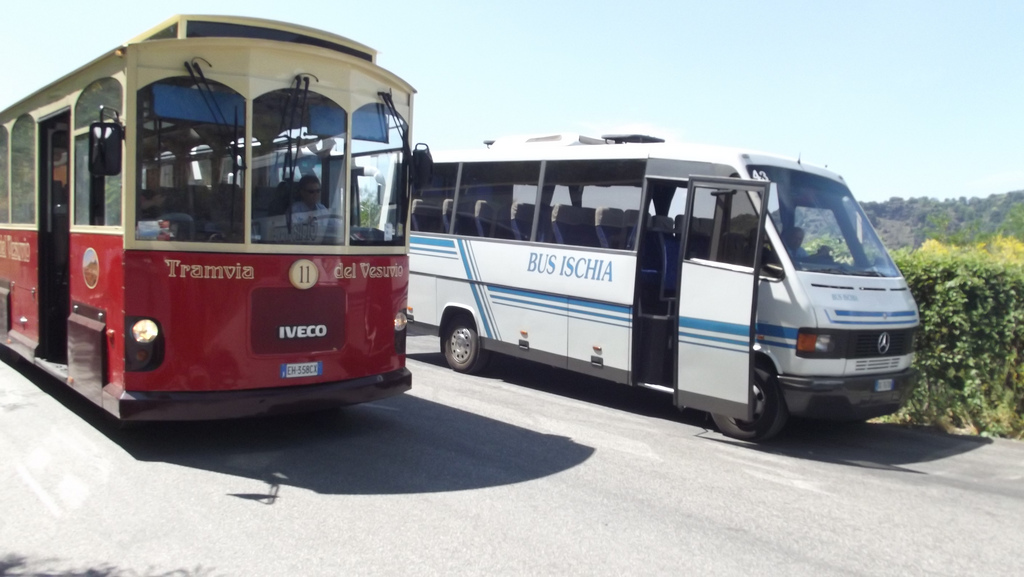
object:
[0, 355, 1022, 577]
road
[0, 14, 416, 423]
bus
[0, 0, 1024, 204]
clouds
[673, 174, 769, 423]
door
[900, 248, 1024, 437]
bush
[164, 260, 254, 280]
writing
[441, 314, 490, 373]
tire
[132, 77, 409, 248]
windshield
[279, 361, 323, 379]
license plate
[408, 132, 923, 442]
bus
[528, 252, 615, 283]
writing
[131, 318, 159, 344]
headlight